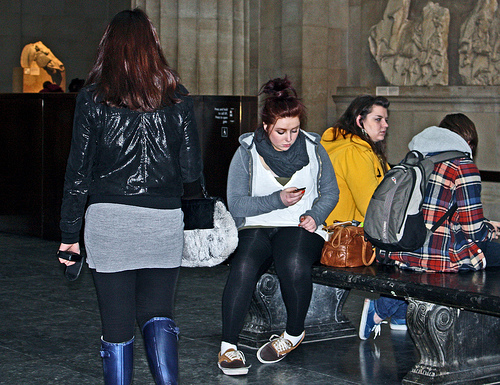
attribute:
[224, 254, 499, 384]
bech — cocrete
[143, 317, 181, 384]
shoe — blue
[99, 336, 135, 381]
shoe — blue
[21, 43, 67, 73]
statue — horse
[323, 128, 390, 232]
sweater — yellow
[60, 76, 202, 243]
jacket — black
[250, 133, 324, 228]
shirt — white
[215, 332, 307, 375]
sneakers — blue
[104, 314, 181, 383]
boots — knee high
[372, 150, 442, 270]
backpack — grey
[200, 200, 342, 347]
pants — black, spandex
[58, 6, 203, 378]
girl — walking